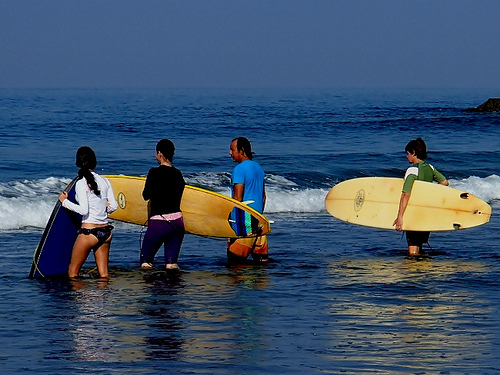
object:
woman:
[57, 145, 118, 278]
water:
[0, 87, 499, 374]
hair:
[74, 146, 100, 196]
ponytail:
[76, 166, 100, 196]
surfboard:
[28, 173, 83, 278]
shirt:
[61, 170, 118, 225]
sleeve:
[101, 176, 118, 213]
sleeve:
[62, 180, 90, 216]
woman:
[139, 136, 188, 271]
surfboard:
[97, 174, 271, 241]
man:
[227, 137, 269, 267]